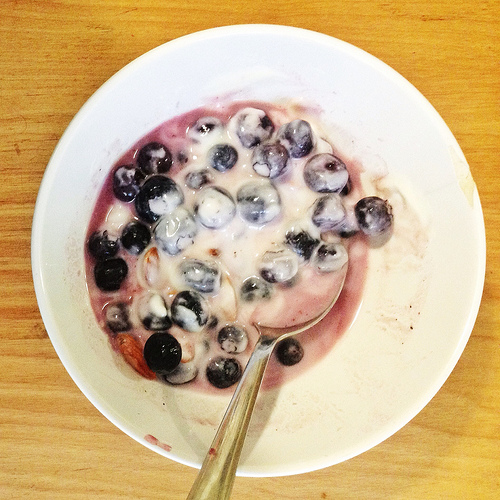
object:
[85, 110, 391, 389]
bunch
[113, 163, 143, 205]
berry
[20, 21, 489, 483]
bowl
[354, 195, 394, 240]
blueberry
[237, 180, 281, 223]
blueberry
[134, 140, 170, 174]
blueberry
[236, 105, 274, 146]
berry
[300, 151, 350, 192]
blueberry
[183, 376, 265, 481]
part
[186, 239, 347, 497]
spoon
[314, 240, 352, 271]
fruit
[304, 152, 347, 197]
fruit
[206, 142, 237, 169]
fruit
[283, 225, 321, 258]
fruit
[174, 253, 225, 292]
fruit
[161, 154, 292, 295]
cream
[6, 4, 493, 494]
table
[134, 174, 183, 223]
blueberry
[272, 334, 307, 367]
blueberry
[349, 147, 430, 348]
cream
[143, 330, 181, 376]
berry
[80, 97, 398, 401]
dessert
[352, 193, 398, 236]
berry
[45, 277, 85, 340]
part